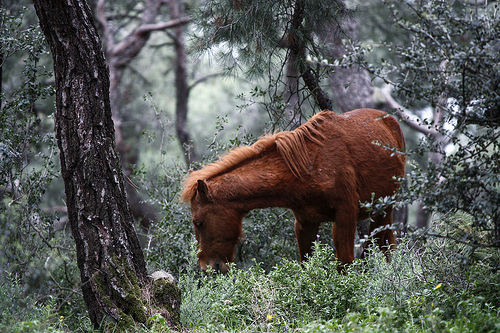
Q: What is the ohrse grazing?
A: Plants.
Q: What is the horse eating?
A: Plants.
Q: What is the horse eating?
A: Vegetation.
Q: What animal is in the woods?
A: Horse.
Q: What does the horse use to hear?
A: Ears.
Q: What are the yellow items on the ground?
A: Flowers.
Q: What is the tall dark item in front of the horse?
A: A tree.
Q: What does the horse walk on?
A: Legs.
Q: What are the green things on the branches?
A: Leaves.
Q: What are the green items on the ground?
A: Bushes.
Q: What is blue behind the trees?
A: Sky.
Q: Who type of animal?
A: Horse.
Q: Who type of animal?
A: Horse.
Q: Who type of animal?
A: Horse.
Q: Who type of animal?
A: Horse.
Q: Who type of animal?
A: Horse.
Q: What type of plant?
A: Tree.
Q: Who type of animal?
A: Horse.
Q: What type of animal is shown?
A: Horse.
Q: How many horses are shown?
A: One.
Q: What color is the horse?
A: Brown.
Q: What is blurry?
A: Background.